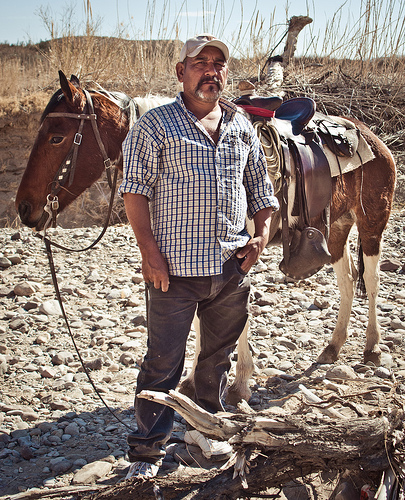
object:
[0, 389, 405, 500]
logs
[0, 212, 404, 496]
rocky ground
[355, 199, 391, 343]
legs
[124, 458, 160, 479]
shoe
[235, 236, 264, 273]
hand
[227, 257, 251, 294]
pocket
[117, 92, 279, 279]
shirt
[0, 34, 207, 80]
hill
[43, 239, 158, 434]
strap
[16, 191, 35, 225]
snout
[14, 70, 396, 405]
horse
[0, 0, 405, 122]
weed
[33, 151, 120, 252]
straps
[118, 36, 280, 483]
man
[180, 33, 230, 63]
cap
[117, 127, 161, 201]
sleeve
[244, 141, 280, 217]
sleeve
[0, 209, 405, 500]
ground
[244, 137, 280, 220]
sleeve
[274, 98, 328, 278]
saddle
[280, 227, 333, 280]
holder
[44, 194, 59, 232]
bit